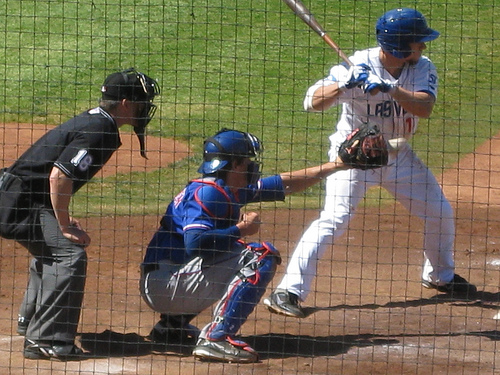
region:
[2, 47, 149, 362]
Umpire is crouching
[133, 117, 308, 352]
Catcher is kneeling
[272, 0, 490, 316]
Baseball player holding bat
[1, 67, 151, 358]
Umpire has black uniform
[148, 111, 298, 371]
Catcher has blue uniform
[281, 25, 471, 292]
Baseball player has white uniform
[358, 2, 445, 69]
Royal blue helmet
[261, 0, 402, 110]
Baseball player holding brown bat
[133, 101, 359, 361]
Catcher extending arm to catch ball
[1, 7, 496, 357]
Three men playing baseball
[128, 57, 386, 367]
this is a fence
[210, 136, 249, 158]
this is a helmet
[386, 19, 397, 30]
the helmet is blue in color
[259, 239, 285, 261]
this is a knee guard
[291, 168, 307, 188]
the man is light skinned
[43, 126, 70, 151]
the t shirt is black in color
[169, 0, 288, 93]
this is grass area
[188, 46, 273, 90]
the grass is green in color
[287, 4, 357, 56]
this is a bat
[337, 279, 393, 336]
this is the ground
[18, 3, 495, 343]
semi-professional baseball players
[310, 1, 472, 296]
plays for a Las Vegas baseball team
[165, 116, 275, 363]
opposing team's uniform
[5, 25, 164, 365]
an umpire in a baseball game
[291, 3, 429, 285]
players getting ready to hit the ball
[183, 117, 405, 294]
catcher ready to receive the ball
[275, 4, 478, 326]
proper technique for hitting a ball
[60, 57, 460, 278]
umpire watching closely watching the action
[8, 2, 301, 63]
nice looking baseball field in the background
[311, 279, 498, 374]
the homeplate can barely be seen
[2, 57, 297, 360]
umpire hunched over behind the catcher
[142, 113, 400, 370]
catcher crouched down with his arm extended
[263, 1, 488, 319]
batter standing in the batter's box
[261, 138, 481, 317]
legs spread wide open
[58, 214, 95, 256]
hand resting on knee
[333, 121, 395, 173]
brown and black catcher's mit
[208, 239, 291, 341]
blue and red shin pads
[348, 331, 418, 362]
white dust in the brown dirt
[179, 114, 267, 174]
blue, shiny hat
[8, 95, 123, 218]
black and white short sleeved shirt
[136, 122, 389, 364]
A catcher playing baseball.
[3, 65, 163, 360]
An umpire at a baseball game.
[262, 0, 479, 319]
A batter with a bat.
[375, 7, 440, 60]
A blue baseball helmet.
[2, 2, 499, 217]
Grass on a field.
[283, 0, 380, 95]
A brown baseball bat.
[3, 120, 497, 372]
Dirt on a baseball field.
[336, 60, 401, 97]
two white and blue gloves.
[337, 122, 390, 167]
A baseball players mitt.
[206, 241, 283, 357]
A catchers knee guard.